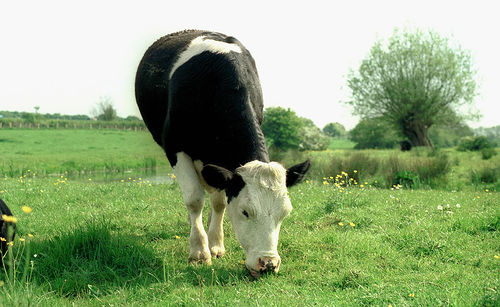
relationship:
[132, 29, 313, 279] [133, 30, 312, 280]
cow eats grass.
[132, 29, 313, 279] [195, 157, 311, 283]
cow has head.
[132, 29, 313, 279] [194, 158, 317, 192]
cow has ears.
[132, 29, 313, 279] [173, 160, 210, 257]
cow has legs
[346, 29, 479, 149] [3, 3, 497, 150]
tree in background.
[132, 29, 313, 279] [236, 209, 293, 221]
cow has eyes.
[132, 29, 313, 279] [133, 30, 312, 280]
cow eating grass.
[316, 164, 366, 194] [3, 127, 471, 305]
flowers amid grass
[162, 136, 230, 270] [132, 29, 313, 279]
legs of cow